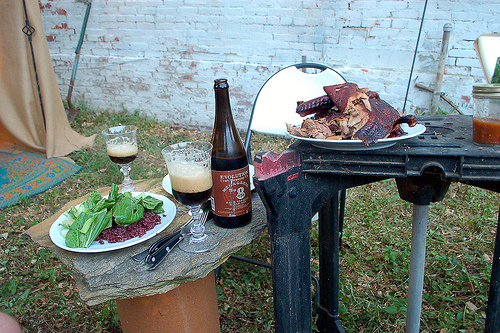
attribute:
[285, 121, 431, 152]
plate — topped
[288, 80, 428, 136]
meat — cooked, barbecued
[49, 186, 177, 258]
plate — topped, round, white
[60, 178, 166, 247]
vegetables — green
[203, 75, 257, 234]
bottle — brown, alcoholic, beer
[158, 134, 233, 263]
glass — filled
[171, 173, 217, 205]
beverage — alcoholic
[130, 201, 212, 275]
utensils — metal, black, silver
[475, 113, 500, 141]
liquid — red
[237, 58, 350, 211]
chair — black, white, folding, metal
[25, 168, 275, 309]
table — makeshift, slate, rock, flat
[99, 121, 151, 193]
glass — clear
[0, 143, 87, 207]
carpet — blue, orange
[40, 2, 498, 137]
wall — white, brick, painted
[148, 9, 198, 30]
bricks — white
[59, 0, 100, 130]
shovel — green, rusty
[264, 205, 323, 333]
leg — metal, black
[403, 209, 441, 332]
leg — metal, white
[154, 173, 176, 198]
dish — empty, white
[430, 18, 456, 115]
pole — metal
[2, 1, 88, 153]
cloth — beige